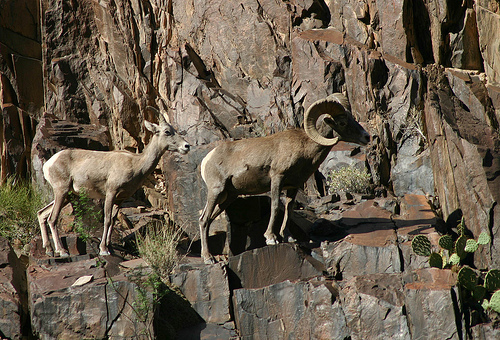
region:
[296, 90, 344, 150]
beige ram horn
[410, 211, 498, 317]
small green cacti growing on rockface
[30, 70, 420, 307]
two goats on rocky hillside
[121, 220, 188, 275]
green grass growing on rocky hillside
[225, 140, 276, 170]
brown fur on side of ram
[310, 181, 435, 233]
shadow of ram on rocks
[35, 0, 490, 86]
large rocky hillface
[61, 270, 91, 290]
small white rock on ground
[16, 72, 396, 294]
two goats standing on rocky cliff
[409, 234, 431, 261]
small cactus leaf covered in thorns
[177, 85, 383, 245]
large horned mountain goat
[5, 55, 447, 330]
mountain goats on mountain side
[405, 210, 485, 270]
cactus on mountain side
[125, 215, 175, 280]
weed on mountain side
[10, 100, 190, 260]
young mountain goat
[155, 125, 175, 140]
eye on younger goat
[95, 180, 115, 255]
front legs of goat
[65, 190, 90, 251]
weed beside goat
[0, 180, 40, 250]
weed behind goat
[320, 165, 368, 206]
flowering weed in front of goat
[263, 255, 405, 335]
sheer rocks on a cliff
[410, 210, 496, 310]
cacti growing in stone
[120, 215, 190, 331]
vegetation in the rock face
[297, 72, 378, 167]
head of a big horn sheep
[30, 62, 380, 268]
male and female animals make their way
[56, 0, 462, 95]
rocks on the mountainside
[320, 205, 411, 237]
shadow cast by the animal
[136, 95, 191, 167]
small horns of the female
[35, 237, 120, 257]
four hooves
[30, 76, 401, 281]
two big horn sheep in their habitat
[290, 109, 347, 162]
Large curved horn on animal.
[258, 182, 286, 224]
Animal has gray leg.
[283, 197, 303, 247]
Animal has gray leg.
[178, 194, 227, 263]
Animal has gray leg.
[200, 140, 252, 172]
Animal has gray rear end.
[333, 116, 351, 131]
Animal has dark eye.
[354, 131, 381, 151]
Animal has dark nose holes.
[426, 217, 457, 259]
Green cacti on side of mountain.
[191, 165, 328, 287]
Animal standing on cliff side.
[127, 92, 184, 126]
Horns on animal's head.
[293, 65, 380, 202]
Ram horns on head.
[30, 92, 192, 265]
Young ram on ledge.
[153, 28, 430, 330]
Rocky landscape used by Rams.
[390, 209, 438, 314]
Catus growing from rock.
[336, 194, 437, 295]
Stone ledge in rock.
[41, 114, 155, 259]
Four legs on ram.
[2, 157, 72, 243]
Bushes growing from rock.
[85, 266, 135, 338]
Cracks in rock wall.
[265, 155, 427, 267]
Rams shadow on rock.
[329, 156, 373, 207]
White buds on the bush.